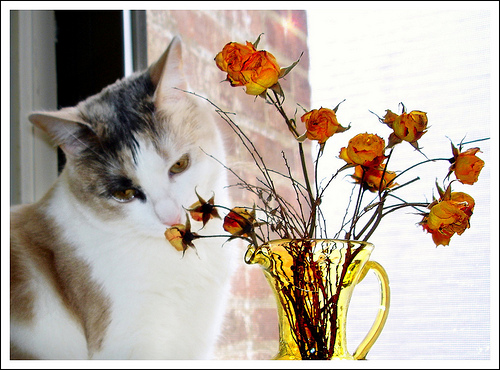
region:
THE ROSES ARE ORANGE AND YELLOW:
[155, 33, 492, 290]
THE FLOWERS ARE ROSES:
[158, 27, 491, 369]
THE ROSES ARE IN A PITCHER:
[149, 26, 489, 356]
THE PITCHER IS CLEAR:
[240, 230, 395, 364]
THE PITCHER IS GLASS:
[241, 223, 393, 366]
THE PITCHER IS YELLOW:
[238, 226, 389, 362]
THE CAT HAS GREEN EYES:
[103, 150, 193, 206]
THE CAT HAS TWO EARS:
[23, 30, 193, 152]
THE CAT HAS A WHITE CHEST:
[88, 202, 240, 362]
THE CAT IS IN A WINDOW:
[8, 26, 242, 357]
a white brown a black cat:
[8, 53, 235, 356]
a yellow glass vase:
[239, 223, 400, 367]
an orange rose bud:
[211, 39, 250, 90]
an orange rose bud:
[156, 224, 194, 249]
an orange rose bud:
[184, 200, 215, 218]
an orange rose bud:
[217, 206, 251, 239]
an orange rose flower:
[214, 39, 253, 85]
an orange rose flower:
[244, 47, 284, 95]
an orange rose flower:
[300, 102, 340, 145]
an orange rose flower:
[342, 132, 385, 167]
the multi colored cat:
[21, 35, 238, 358]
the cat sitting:
[13, 35, 236, 360]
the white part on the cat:
[130, 250, 215, 364]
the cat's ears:
[23, 29, 195, 139]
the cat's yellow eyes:
[87, 146, 195, 204]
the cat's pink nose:
[157, 202, 182, 227]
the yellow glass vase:
[231, 218, 391, 365]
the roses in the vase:
[167, 31, 484, 268]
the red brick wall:
[238, 104, 283, 152]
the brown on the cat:
[19, 214, 44, 254]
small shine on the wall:
[271, 14, 301, 31]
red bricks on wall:
[201, 8, 309, 56]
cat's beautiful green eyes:
[158, 146, 200, 175]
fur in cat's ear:
[40, 119, 87, 138]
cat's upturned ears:
[16, 105, 111, 157]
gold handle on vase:
[361, 258, 395, 349]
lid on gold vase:
[232, 221, 407, 252]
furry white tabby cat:
[52, 24, 267, 326]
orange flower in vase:
[410, 177, 483, 254]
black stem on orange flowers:
[168, 191, 271, 253]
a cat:
[69, 100, 276, 367]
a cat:
[164, 172, 267, 323]